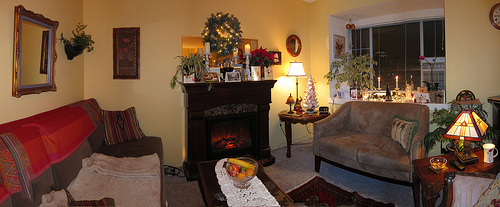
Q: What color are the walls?
A: Yellow.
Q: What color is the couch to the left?
A: Red.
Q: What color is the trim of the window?
A: White.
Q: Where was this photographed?
A: Living room.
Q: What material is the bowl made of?
A: Glass.